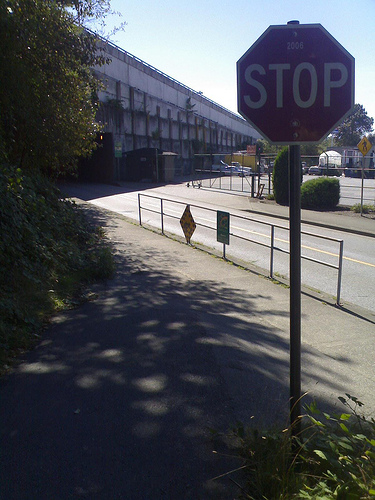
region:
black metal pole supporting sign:
[284, 141, 305, 462]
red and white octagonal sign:
[235, 20, 360, 144]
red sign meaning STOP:
[232, 19, 361, 142]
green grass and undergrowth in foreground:
[202, 393, 372, 491]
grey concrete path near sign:
[7, 192, 371, 485]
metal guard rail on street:
[133, 190, 354, 311]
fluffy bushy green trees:
[1, 0, 127, 366]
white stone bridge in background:
[63, 6, 263, 187]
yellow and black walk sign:
[355, 132, 373, 213]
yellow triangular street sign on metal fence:
[179, 200, 198, 248]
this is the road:
[90, 184, 122, 199]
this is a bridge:
[117, 49, 136, 164]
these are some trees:
[4, 0, 89, 169]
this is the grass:
[15, 220, 75, 266]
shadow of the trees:
[120, 259, 256, 401]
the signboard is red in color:
[269, 42, 279, 54]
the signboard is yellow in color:
[360, 138, 370, 154]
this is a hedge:
[306, 174, 340, 212]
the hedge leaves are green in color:
[307, 181, 328, 200]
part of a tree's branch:
[5, 78, 99, 160]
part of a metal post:
[279, 194, 310, 304]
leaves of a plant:
[269, 437, 362, 482]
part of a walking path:
[98, 306, 192, 408]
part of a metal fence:
[185, 201, 261, 272]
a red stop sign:
[245, 39, 317, 130]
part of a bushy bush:
[0, 150, 81, 286]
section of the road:
[346, 242, 373, 285]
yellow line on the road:
[349, 249, 373, 268]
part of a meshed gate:
[182, 144, 242, 194]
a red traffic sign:
[227, 20, 355, 154]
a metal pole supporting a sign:
[285, 145, 326, 456]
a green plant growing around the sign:
[262, 406, 349, 496]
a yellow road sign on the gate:
[176, 201, 197, 253]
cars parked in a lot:
[216, 158, 252, 181]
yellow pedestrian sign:
[358, 131, 374, 217]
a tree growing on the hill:
[13, 12, 96, 165]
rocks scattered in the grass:
[18, 201, 80, 274]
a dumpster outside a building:
[125, 146, 169, 182]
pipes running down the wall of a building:
[145, 107, 199, 146]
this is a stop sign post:
[237, 35, 344, 136]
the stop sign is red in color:
[237, 31, 352, 143]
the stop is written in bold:
[242, 64, 346, 111]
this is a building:
[105, 90, 211, 144]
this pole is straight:
[289, 147, 300, 407]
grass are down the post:
[222, 416, 357, 498]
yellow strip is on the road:
[350, 250, 370, 268]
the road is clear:
[345, 245, 372, 295]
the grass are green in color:
[235, 416, 363, 496]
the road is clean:
[347, 244, 365, 302]